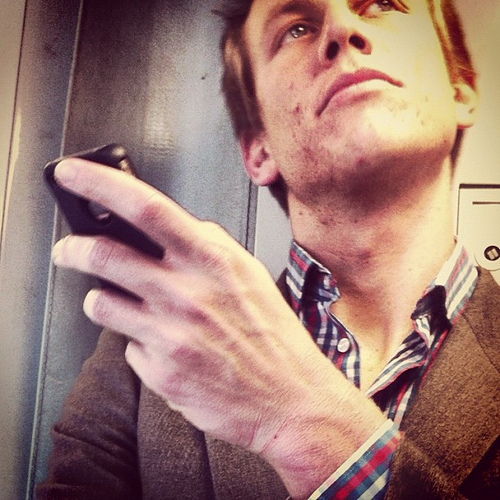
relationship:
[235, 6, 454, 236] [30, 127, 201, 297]
man holding cell phone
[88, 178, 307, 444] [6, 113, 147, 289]
hand holding cell phone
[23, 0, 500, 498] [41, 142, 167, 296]
man holding cell phone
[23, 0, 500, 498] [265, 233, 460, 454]
man wearing shirt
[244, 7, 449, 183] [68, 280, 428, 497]
man wearing coat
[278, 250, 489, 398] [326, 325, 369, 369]
shirt has buttons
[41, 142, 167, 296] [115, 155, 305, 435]
cell phone in mans hand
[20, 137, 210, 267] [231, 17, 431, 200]
index finger of man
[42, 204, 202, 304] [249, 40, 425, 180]
middle finger of man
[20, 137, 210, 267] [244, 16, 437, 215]
index finger of man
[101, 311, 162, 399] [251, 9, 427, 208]
pinky finger of man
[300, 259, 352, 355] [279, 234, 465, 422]
buttons on shirt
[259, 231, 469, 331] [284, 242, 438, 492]
collar of shirt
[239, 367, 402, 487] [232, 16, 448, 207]
wrist of man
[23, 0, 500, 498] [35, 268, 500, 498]
man wearing coat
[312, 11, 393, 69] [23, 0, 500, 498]
nose of man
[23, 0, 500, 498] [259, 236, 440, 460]
man in shirt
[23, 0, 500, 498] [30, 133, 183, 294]
man holding cell phone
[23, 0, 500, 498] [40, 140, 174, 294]
man holding cellphone